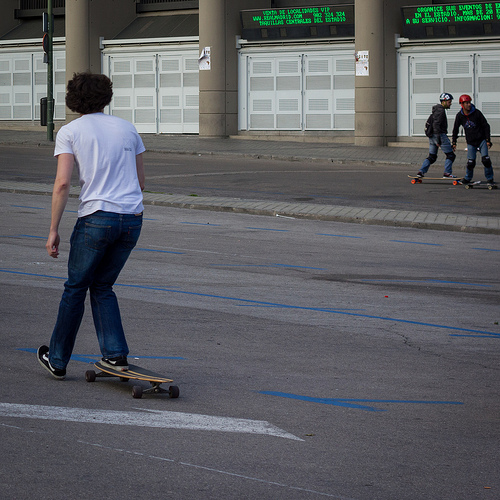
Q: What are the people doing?
A: Skateboarding.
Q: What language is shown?
A: Spanish.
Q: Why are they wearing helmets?
A: Safety.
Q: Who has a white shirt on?
A: Person on left.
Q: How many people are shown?
A: Three.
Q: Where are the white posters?
A: On the poles.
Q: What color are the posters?
A: White and black.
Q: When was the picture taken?
A: During daytime.